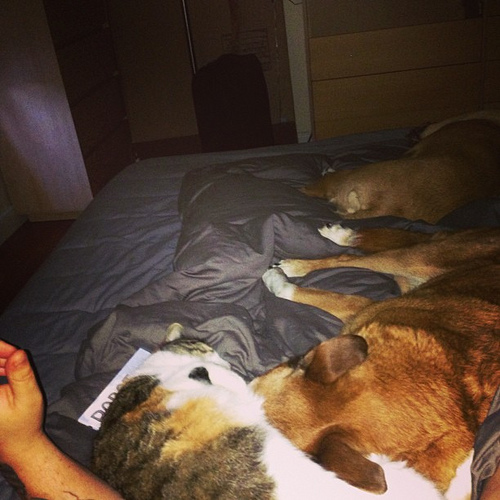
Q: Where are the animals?
A: On the bed.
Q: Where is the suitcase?
A: Next to the AC vent.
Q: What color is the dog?
A: Brown.